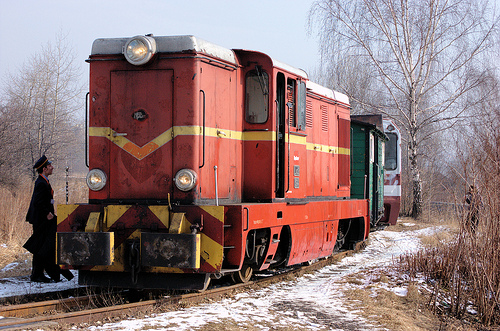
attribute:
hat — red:
[30, 145, 59, 174]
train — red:
[93, 73, 177, 192]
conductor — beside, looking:
[25, 153, 86, 271]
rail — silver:
[37, 299, 133, 329]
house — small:
[57, 163, 106, 213]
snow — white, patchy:
[274, 267, 347, 310]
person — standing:
[454, 188, 494, 232]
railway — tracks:
[22, 286, 230, 329]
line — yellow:
[91, 117, 221, 158]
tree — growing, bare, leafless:
[351, 1, 480, 192]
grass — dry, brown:
[8, 197, 44, 238]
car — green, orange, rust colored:
[355, 131, 393, 196]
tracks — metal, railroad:
[25, 296, 78, 331]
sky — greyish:
[33, 11, 143, 68]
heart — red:
[111, 135, 194, 202]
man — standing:
[23, 148, 69, 244]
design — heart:
[98, 114, 170, 192]